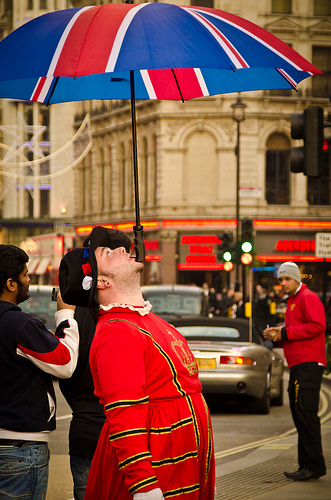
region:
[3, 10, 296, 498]
Man balancing umbrella on chin.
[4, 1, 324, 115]
Red, white and blue umbrella.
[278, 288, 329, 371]
Man wearing red jacket.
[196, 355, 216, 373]
Tag on rear of car.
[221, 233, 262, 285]
A traffic light on corner.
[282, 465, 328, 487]
Man wearing black boots.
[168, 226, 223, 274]
Red sign above store.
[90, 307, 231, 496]
Man wearing red outfit with black and gold stripes.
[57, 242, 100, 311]
Man wearing black hat with red, white and blue objects.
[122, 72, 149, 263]
Black handle of umbrella.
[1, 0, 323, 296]
man holding umbrella with his chin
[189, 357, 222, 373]
yellow license plate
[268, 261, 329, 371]
man in white jacket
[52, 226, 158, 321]
man in black hat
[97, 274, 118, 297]
man with earring in ear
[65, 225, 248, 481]
man wearing red dress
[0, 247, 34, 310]
man with beard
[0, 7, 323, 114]
red, white, and blue umbrella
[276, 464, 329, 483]
man with pointed toe shoes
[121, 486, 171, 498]
man wearing white glove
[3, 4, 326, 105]
Umbrella with Union Jack-like pattern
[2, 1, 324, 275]
Man balancing umbrella on chin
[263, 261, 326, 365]
Man wearing red jacket and grey cap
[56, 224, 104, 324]
Hat with blue, red and white flowers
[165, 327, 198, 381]
Crown on chest of red costume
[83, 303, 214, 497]
Queen of English body guard costume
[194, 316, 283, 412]
Sand-color convertible on a street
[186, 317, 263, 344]
Black convertible soft top seen in traffic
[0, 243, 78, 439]
Man wearing blue jacket with blue, red and white sleeve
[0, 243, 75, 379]
Man with beard holding a camera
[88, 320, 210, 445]
the uniform is red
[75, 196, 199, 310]
handle of the umbrella is on man's mouth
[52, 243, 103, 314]
the hat is black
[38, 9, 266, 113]
umbrella is blue, white and red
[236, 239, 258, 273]
traffic light is green and yellow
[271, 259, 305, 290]
knit cap is gray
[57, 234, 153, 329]
man is looking up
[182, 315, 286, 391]
the car is silver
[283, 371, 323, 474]
the pants is black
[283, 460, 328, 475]
the shoes is black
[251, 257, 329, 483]
Man wearing red jacket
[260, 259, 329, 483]
man wearing black pants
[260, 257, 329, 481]
man wearing black shoes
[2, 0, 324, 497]
Red and Blue umbrella balancing on mans chin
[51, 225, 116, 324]
black hat with flowers on mans head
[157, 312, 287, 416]
the car is a metallic color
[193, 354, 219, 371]
license plate is yellow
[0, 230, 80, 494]
man taking a picture with his phone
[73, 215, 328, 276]
Neon lights are red.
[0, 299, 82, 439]
Jacket is red, white and dark blue